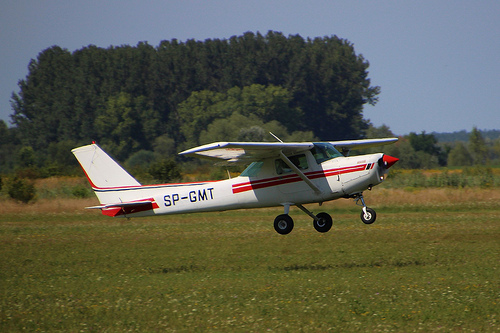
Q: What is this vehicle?
A: Plane.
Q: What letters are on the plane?
A: SP-GMT.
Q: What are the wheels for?
A: To land.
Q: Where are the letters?
A: On the plane's body.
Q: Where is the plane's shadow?
A: On the grass.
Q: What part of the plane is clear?
A: The window.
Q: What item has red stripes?
A: The plane.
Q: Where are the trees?
A: On the other side of the field.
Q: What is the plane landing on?
A: Grass.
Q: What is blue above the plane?
A: The sky.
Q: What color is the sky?
A: Blue gray.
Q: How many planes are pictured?
A: One.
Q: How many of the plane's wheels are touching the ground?
A: Zero.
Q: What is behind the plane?
A: Trees.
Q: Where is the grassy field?
A: Below the plane.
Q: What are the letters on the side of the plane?
A: SP-GMT.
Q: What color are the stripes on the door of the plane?
A: Red.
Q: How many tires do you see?
A: Three.